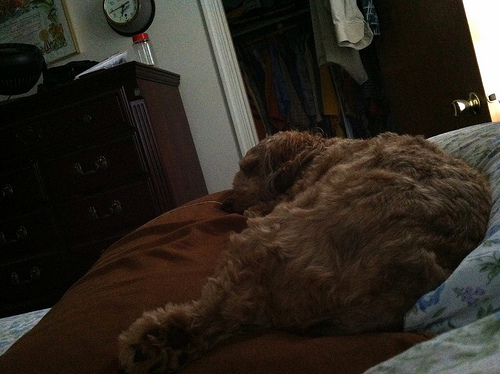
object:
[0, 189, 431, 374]
red sheets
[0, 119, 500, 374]
bed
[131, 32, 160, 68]
bottle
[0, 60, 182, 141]
table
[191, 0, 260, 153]
wood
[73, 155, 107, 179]
handle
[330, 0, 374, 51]
white shirt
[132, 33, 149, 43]
lid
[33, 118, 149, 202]
dresser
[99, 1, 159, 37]
clock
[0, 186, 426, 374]
brown blanket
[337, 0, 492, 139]
door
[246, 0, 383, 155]
clothes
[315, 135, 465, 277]
furry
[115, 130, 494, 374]
brown dog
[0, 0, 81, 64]
certificate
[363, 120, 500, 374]
pillow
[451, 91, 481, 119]
handle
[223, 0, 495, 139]
closet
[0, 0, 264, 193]
wall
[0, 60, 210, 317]
cabinet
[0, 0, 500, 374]
room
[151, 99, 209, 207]
wood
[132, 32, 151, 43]
top